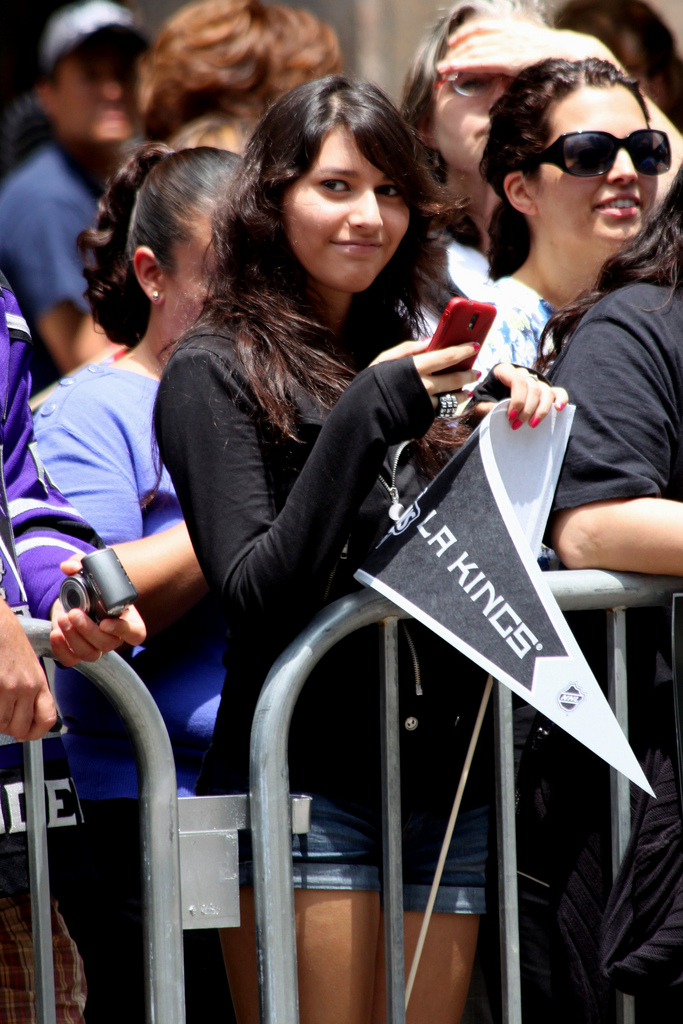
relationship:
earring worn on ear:
[146, 283, 162, 300] [127, 240, 169, 304]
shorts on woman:
[147, 751, 524, 925] [156, 69, 581, 1022]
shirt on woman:
[147, 286, 524, 817] [156, 69, 581, 1022]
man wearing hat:
[3, 2, 159, 380] [3, 2, 159, 82]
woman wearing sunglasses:
[469, 54, 678, 388] [469, 119, 678, 194]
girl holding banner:
[143, 48, 550, 1021] [331, 373, 666, 835]